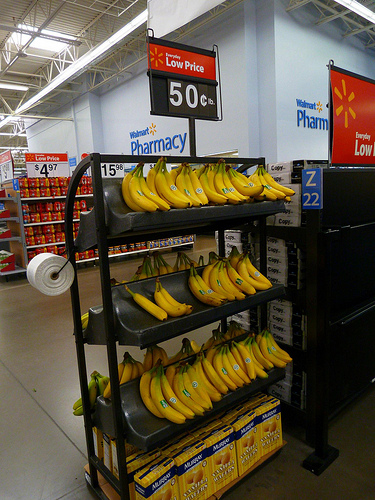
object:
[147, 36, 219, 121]
sign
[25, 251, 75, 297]
bags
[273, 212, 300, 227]
paper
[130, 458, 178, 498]
cookies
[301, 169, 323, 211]
sign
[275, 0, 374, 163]
wall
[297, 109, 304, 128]
lettering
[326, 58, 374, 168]
sign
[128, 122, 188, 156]
pharmacy sign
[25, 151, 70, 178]
sign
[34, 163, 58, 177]
$4.97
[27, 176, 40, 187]
coffee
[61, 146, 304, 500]
rack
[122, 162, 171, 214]
bunch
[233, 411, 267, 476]
vanilla wafers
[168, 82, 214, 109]
price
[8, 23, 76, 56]
skylight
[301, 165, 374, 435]
row z22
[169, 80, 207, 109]
50 cents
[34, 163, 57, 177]
price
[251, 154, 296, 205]
products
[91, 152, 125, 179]
sign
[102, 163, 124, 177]
$15.98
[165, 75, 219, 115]
price tag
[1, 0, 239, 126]
roof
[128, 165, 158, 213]
bananas